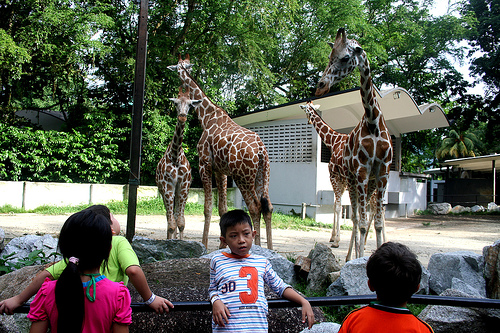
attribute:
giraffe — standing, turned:
[168, 55, 275, 254]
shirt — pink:
[28, 273, 131, 332]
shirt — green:
[47, 234, 139, 285]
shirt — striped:
[210, 250, 293, 333]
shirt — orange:
[337, 301, 432, 332]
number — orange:
[238, 265, 260, 304]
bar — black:
[1, 293, 500, 311]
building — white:
[232, 86, 451, 221]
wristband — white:
[211, 295, 221, 304]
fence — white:
[1, 179, 237, 214]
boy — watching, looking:
[340, 242, 436, 332]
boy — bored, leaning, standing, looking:
[207, 209, 313, 332]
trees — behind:
[1, 1, 500, 182]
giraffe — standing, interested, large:
[314, 25, 389, 265]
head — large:
[317, 25, 364, 97]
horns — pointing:
[334, 26, 350, 43]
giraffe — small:
[156, 94, 201, 242]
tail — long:
[258, 151, 270, 215]